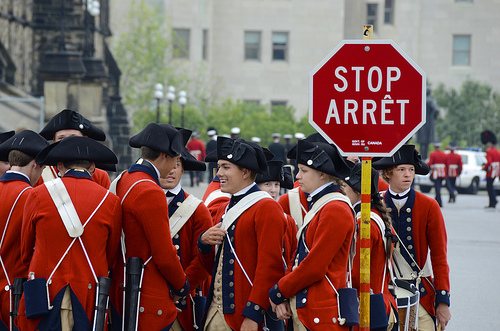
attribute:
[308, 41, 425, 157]
sign — red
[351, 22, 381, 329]
pole — yellow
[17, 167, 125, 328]
jacket — red 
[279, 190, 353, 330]
jacket — red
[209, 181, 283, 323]
jacket — red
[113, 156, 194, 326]
jacket — red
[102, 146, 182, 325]
jacket — red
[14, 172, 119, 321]
jacket — red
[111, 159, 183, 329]
jacket — red